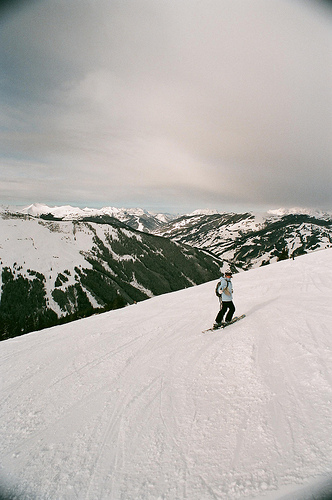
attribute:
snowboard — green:
[205, 315, 243, 333]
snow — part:
[6, 205, 326, 495]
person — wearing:
[212, 269, 238, 329]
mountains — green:
[0, 206, 330, 341]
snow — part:
[94, 353, 216, 431]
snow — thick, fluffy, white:
[283, 262, 311, 306]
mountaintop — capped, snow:
[153, 211, 179, 221]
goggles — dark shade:
[219, 276, 240, 288]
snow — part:
[281, 268, 286, 274]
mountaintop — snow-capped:
[29, 208, 145, 212]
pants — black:
[204, 302, 264, 338]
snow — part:
[255, 279, 301, 307]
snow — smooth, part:
[0, 248, 331, 499]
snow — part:
[154, 356, 275, 456]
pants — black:
[212, 300, 237, 325]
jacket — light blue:
[207, 277, 242, 311]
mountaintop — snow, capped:
[0, 202, 331, 222]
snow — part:
[8, 221, 82, 273]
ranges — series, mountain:
[8, 211, 329, 341]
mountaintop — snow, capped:
[194, 208, 215, 215]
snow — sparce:
[2, 205, 329, 351]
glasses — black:
[225, 272, 231, 275]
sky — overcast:
[0, 1, 330, 209]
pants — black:
[218, 300, 232, 325]